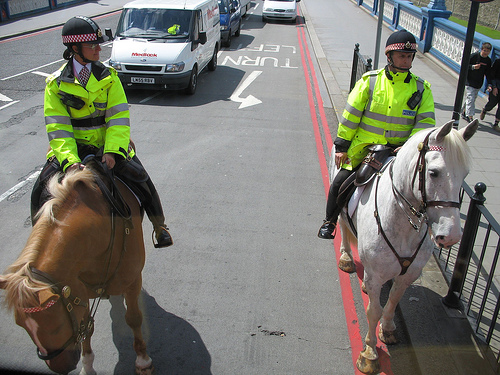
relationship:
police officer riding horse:
[30, 17, 173, 250] [4, 162, 150, 369]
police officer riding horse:
[321, 28, 435, 238] [332, 122, 478, 371]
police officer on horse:
[30, 17, 173, 250] [4, 162, 150, 369]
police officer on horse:
[321, 28, 435, 238] [332, 122, 478, 371]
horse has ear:
[332, 122, 478, 371] [431, 121, 452, 142]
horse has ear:
[332, 122, 478, 371] [460, 118, 478, 141]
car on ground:
[262, 0, 299, 24] [1, 6, 425, 373]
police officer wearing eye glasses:
[30, 17, 173, 250] [83, 42, 97, 49]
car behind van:
[218, 3, 243, 46] [105, 1, 223, 95]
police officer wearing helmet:
[30, 17, 173, 250] [60, 16, 101, 41]